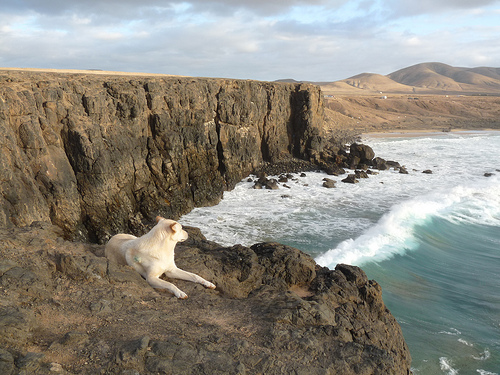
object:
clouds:
[158, 29, 184, 58]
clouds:
[307, 48, 397, 68]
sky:
[5, 0, 48, 27]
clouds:
[197, 4, 278, 16]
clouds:
[234, 22, 301, 65]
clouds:
[293, 25, 334, 55]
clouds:
[82, 8, 141, 27]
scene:
[10, 1, 499, 372]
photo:
[5, 4, 493, 373]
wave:
[324, 175, 462, 280]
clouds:
[74, 10, 108, 37]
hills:
[330, 51, 499, 101]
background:
[9, 46, 492, 113]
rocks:
[265, 141, 413, 186]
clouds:
[415, 13, 464, 47]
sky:
[415, 2, 459, 66]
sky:
[56, 47, 85, 67]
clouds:
[340, 10, 490, 20]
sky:
[454, 8, 494, 78]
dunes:
[436, 61, 496, 99]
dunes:
[301, 55, 384, 96]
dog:
[92, 210, 232, 308]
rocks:
[330, 323, 396, 371]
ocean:
[411, 294, 497, 373]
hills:
[271, 77, 299, 81]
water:
[155, 130, 491, 371]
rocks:
[248, 111, 266, 127]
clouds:
[1, 2, 41, 41]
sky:
[384, 2, 411, 74]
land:
[454, 119, 482, 122]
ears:
[167, 221, 181, 232]